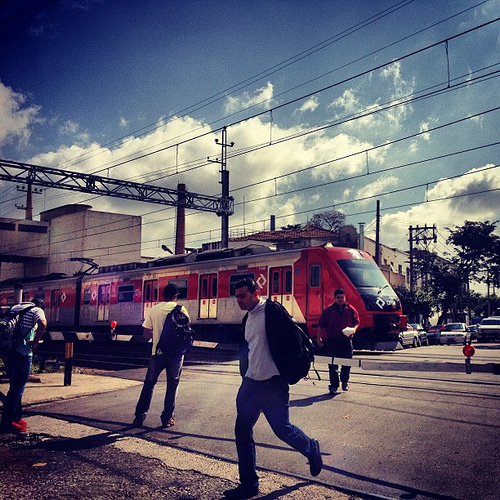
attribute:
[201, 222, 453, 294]
building — brick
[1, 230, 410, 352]
train — red, red and silver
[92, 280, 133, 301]
window — small, silver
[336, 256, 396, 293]
window — small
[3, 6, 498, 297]
sky — blue 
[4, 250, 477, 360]
train — white, red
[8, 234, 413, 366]
train — red, passenger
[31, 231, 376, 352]
train — red 